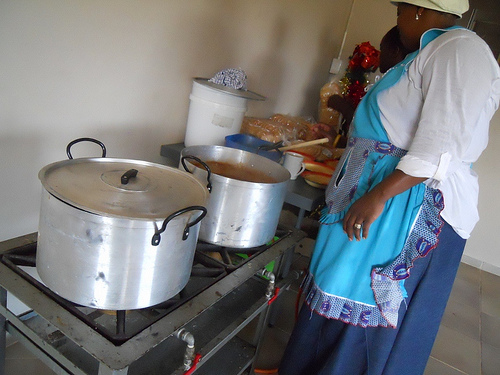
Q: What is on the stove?
A: Pots.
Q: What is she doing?
A: Cooking.